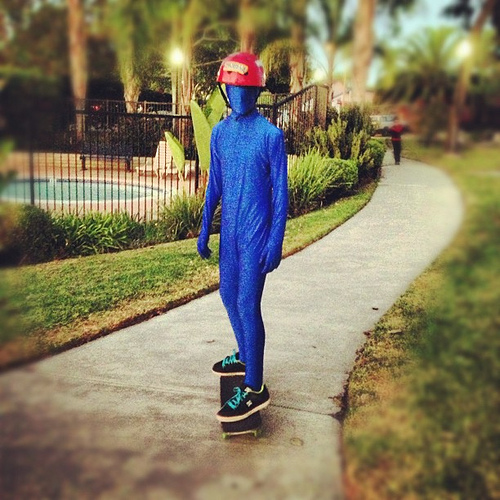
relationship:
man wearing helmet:
[196, 53, 289, 422] [217, 51, 267, 90]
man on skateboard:
[196, 53, 289, 422] [219, 377, 263, 441]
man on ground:
[392, 117, 403, 164] [1, 144, 496, 500]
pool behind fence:
[2, 179, 167, 205] [2, 83, 330, 222]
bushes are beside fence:
[2, 104, 378, 267] [2, 83, 330, 222]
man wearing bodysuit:
[196, 53, 289, 422] [199, 89, 287, 383]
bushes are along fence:
[2, 104, 378, 267] [2, 83, 330, 222]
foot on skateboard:
[217, 388, 271, 423] [219, 377, 263, 441]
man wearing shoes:
[196, 53, 289, 422] [211, 356, 273, 422]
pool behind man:
[2, 179, 167, 205] [196, 53, 289, 422]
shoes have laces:
[211, 356, 273, 422] [227, 385, 246, 407]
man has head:
[196, 53, 289, 422] [217, 53, 267, 118]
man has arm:
[196, 53, 289, 422] [262, 129, 285, 275]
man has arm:
[196, 53, 289, 422] [196, 128, 221, 258]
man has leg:
[196, 53, 289, 422] [238, 240, 269, 389]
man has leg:
[196, 53, 289, 422] [218, 246, 242, 360]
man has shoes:
[196, 53, 289, 422] [211, 356, 273, 422]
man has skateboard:
[196, 53, 289, 422] [219, 377, 263, 441]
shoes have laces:
[211, 356, 273, 422] [223, 350, 240, 369]